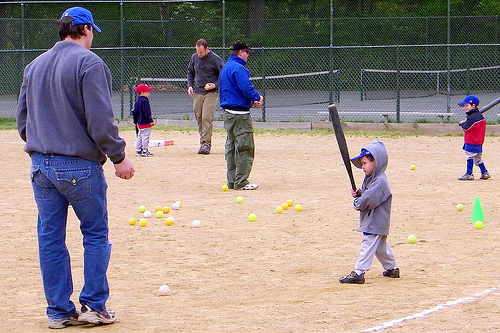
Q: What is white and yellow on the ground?
A: Baseballs.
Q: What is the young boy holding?
A: A baseball bat.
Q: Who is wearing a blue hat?
A: The man.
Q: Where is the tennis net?
A: Behind the fence.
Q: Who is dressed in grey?
A: The little boy.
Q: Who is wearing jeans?
A: The man.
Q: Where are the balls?
A: On the ground.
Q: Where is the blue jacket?
A: On the man.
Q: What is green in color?
A: The cone.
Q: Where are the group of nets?
A: Behind the fence on the tennis court.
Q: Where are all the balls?
A: On the ground.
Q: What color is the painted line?
A: White.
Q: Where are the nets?
A: On the tennis court.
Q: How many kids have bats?
A: Two.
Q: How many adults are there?
A: Three.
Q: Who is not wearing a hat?
A: The man with the tan pants.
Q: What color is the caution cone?
A: Neon Green.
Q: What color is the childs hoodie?
A: Grey.